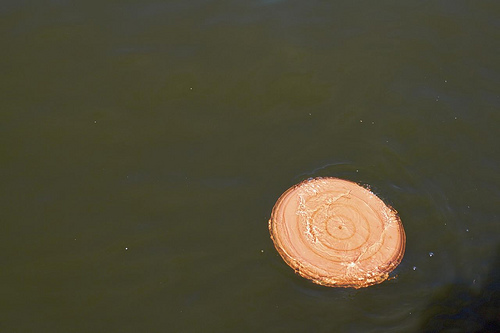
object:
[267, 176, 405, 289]
frisbee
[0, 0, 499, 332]
water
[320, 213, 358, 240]
lines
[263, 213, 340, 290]
edge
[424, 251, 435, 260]
air bubbles